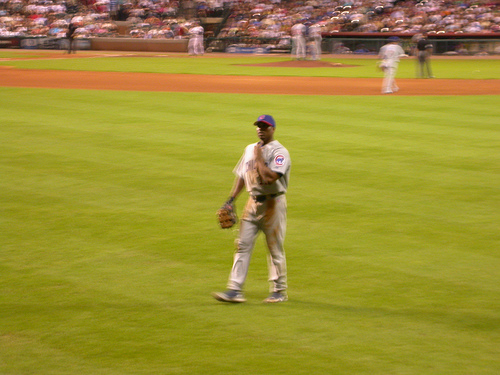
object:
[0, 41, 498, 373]
baseball field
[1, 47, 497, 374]
field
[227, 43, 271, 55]
advertisement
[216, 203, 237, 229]
gloves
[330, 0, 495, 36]
public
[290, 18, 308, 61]
baseball player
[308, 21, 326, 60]
baseball player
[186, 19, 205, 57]
baseball player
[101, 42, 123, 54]
home plate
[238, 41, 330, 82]
mound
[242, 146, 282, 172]
chest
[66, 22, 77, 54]
man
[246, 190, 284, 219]
buckle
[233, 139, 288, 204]
shirt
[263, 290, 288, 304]
shoe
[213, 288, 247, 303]
shoe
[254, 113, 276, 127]
cap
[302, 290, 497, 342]
shadow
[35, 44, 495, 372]
grass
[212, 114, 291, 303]
baseball player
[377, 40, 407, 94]
baseball player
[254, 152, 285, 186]
arm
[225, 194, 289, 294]
pants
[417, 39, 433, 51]
clothes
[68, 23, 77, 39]
clothes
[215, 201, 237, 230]
hand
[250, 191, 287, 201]
belt